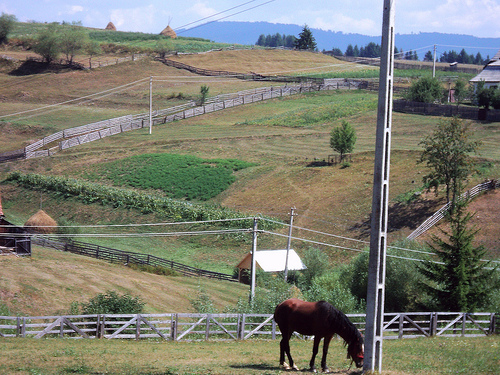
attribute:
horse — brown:
[248, 279, 374, 369]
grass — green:
[132, 155, 224, 187]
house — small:
[233, 243, 305, 286]